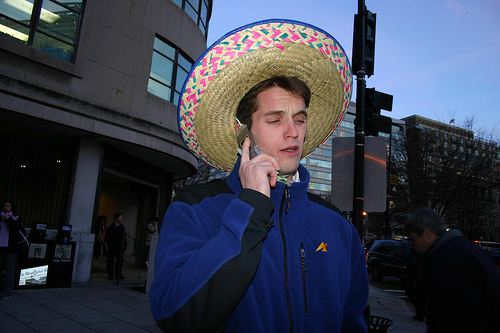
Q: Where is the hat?
A: On the mans head.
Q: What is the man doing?
A: Talking on the phone.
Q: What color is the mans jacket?
A: Blue.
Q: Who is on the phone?
A: A man.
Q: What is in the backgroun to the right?
A: Tree.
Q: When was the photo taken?
A: Near evening.